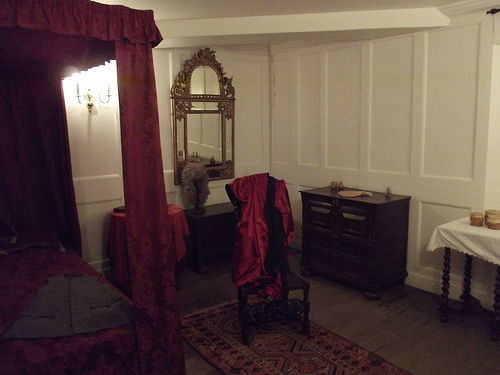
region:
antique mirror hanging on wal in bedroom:
[170, 45, 235, 187]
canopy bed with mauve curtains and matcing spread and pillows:
[1, 0, 187, 373]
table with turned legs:
[426, 209, 499, 341]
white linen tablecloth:
[424, 213, 499, 266]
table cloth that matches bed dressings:
[106, 204, 193, 289]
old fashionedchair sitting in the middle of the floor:
[223, 171, 314, 348]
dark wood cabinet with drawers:
[296, 178, 413, 303]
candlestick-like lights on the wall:
[73, 58, 113, 117]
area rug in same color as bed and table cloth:
[178, 291, 413, 373]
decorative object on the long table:
[181, 155, 211, 218]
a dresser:
[301, 175, 411, 297]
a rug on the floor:
[237, 344, 324, 373]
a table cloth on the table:
[447, 228, 482, 248]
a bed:
[1, 246, 93, 334]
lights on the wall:
[68, 83, 115, 108]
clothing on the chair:
[222, 183, 294, 286]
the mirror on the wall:
[176, 100, 237, 171]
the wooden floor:
[355, 302, 426, 344]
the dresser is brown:
[303, 180, 401, 293]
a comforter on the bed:
[5, 263, 112, 331]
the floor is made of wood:
[336, 291, 435, 349]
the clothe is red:
[226, 177, 303, 297]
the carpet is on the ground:
[185, 304, 382, 374]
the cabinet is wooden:
[307, 175, 411, 301]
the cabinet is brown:
[298, 181, 406, 291]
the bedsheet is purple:
[17, 234, 92, 373]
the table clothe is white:
[434, 216, 498, 266]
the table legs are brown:
[427, 260, 497, 323]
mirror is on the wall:
[184, 83, 229, 166]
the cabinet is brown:
[180, 199, 249, 265]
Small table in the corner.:
[438, 203, 496, 255]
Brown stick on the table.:
[432, 235, 462, 337]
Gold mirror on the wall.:
[164, 51, 255, 182]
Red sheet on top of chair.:
[228, 171, 308, 301]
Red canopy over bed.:
[5, 1, 187, 332]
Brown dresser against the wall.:
[310, 178, 404, 283]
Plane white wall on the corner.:
[300, 21, 445, 133]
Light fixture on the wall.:
[68, 76, 119, 124]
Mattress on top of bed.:
[31, 228, 93, 320]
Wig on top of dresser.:
[167, 155, 228, 220]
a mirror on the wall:
[93, 11, 424, 225]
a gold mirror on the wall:
[139, 39, 354, 271]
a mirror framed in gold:
[169, 44, 371, 300]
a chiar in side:
[187, 146, 327, 366]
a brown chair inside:
[162, 143, 352, 360]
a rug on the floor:
[136, 218, 366, 373]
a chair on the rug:
[179, 138, 388, 364]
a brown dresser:
[272, 129, 486, 303]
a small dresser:
[275, 147, 487, 348]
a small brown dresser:
[237, 123, 498, 362]